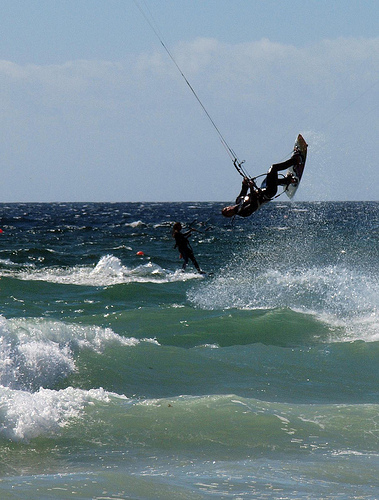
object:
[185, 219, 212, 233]
handle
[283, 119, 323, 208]
board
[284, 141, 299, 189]
feet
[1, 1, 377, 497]
photo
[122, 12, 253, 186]
rope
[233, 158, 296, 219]
swimsuit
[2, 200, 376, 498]
sea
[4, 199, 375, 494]
waves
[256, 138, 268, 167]
ground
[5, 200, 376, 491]
water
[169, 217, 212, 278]
man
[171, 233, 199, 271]
suit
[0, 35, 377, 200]
clouds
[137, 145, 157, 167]
wall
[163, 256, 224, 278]
board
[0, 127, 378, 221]
mid air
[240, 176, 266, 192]
handlebar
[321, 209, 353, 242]
waves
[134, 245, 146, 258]
ball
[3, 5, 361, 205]
sky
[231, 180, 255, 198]
man strings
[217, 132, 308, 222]
man